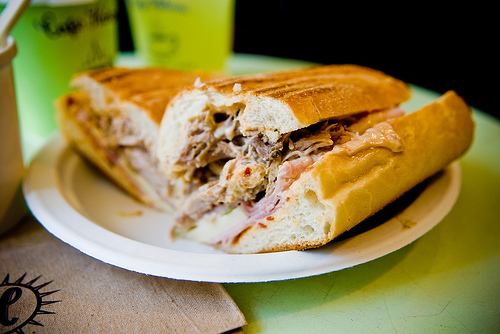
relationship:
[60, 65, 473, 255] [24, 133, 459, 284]
sandwich on plate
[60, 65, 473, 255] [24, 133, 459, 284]
sandwich on a plate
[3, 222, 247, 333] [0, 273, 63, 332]
napkin has a logo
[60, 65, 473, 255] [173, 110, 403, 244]
sandwich has meat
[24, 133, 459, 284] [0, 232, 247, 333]
plate made of napkin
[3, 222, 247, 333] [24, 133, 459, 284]
napkin under plate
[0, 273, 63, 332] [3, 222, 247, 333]
logo on napkin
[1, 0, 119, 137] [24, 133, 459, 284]
cup behind plate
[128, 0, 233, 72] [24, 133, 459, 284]
cup behind plate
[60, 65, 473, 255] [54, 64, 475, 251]
sandwich has bread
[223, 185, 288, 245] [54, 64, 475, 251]
sauce on bread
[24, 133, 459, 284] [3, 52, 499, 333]
plate on table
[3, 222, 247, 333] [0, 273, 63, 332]
napkin has logo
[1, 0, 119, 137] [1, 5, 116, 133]
cup has drink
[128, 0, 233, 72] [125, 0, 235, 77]
cup has drink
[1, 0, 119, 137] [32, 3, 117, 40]
cup has writing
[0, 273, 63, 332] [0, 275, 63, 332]
logo shaped like a star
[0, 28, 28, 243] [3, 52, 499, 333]
jar on table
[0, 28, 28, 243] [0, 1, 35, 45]
jar has a laddle